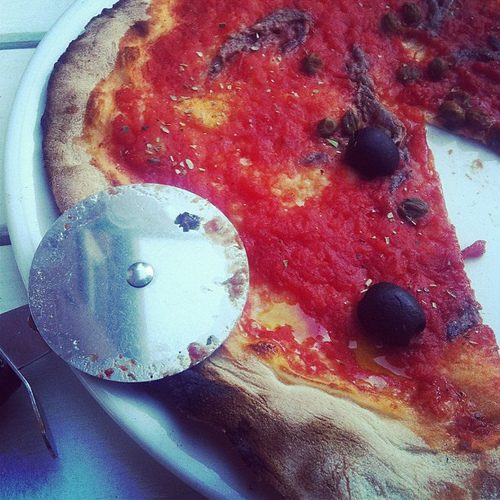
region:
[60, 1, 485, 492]
a cheese pita with olives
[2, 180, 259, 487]
a pizza cutter with grime on it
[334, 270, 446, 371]
a black olive on some cheese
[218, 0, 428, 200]
burnt marks on a cheese topping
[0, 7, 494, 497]
a white plate with some food on it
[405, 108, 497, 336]
an empty spot where a slice of food was cut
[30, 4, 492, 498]
cheese pita with missing slice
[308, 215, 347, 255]
sauce on the pizza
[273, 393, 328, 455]
the crust is brown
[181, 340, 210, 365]
sauce on the pizza cutter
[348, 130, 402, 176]
olives on the pizza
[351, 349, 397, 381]
liquid in the sauce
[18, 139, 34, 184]
the plate is white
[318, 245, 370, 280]
red sauce on the pizza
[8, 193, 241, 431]
pizza cutter on the plate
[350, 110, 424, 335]
black olives on the pizza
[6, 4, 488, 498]
plate the pizza is on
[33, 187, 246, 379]
sauce on the pizza cutter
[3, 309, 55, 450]
handle of the pizza cutter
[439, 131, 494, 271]
crumbs on the plate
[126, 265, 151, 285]
bolt on the pizza cutter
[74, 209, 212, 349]
reflection on pizza cutter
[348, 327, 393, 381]
grease on the pizza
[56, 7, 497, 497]
this is a pizza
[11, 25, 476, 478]
the plate is white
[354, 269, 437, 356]
fruit topping on the pizza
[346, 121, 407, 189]
fruit topping on the pizza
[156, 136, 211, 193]
these are small seeds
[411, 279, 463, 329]
these are small seeds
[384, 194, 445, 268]
these are small seeds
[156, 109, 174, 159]
these are small seeds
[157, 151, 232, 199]
these are small seeds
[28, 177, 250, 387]
round wheel of a pizza cutter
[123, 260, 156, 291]
fastener of a pizza cutter wheel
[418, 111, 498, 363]
pan showing where pizza is missing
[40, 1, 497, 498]
pizza on a pan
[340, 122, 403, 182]
black olive farthest from the camera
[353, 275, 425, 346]
black olive closest to the camera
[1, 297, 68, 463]
handle of the pizza cutter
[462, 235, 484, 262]
crumb on the pizza pan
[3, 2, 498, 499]
pizza pan on a surface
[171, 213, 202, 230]
black food on the cutting wheel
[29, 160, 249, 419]
pizza cutter is silver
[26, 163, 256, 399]
pizza cutter is silver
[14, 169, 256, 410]
pizza cutter is silver